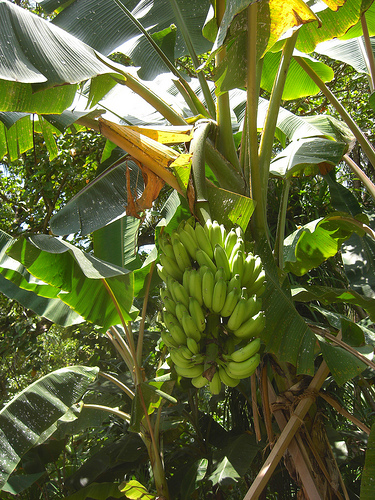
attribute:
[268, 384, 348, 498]
rope — pieces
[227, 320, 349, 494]
planks — wooden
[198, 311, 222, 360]
stem — green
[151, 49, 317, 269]
plant stalks — large, green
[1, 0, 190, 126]
leaf — large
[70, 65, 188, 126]
sunlight — bright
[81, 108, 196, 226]
yellow leaf — small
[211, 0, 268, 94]
leaf — dead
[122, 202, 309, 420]
bananas — bunch, green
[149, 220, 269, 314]
bananas. — bunch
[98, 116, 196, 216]
leaf — light brown dry tropical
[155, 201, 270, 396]
bananas — bunches, unripe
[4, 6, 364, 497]
tree — branch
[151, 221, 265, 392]
banana — bunch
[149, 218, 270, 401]
bananas — large , bunch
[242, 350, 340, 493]
wood — dead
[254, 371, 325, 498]
post — wooden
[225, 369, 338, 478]
planks — wood